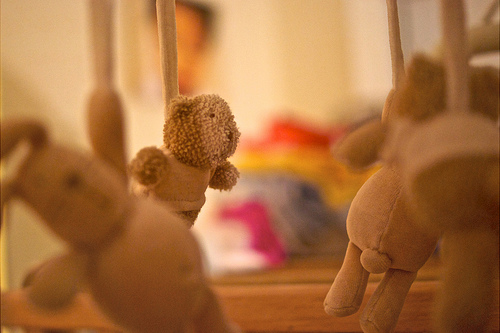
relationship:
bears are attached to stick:
[13, 10, 232, 330] [142, 8, 185, 109]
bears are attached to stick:
[327, 51, 498, 324] [376, 0, 414, 80]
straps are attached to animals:
[80, 11, 482, 89] [3, 36, 468, 313]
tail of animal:
[354, 246, 402, 275] [325, 44, 462, 331]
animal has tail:
[322, 54, 492, 329] [358, 245, 394, 283]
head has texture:
[158, 84, 243, 171] [165, 84, 237, 177]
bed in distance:
[234, 121, 365, 285] [181, 51, 421, 280]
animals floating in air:
[4, 47, 494, 330] [7, 44, 496, 331]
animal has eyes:
[117, 80, 254, 223] [200, 108, 243, 132]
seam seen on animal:
[378, 174, 411, 271] [312, 51, 470, 322]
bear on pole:
[138, 94, 247, 222] [149, 2, 196, 110]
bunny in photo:
[12, 88, 240, 330] [2, 4, 498, 329]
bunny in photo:
[306, 40, 458, 330] [14, 37, 495, 330]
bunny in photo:
[306, 40, 458, 330] [2, 4, 498, 329]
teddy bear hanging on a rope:
[128, 93, 240, 226] [154, 0, 184, 115]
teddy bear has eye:
[128, 93, 240, 226] [208, 110, 217, 120]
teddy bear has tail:
[322, 52, 499, 332] [358, 246, 395, 276]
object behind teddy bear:
[188, 113, 380, 275] [128, 93, 240, 226]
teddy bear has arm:
[128, 93, 240, 226] [126, 144, 169, 190]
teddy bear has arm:
[128, 93, 240, 226] [208, 163, 242, 190]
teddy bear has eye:
[128, 93, 240, 226] [206, 110, 218, 120]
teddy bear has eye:
[0, 85, 234, 331] [30, 168, 52, 187]